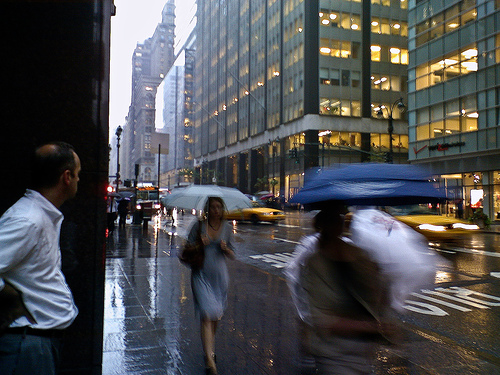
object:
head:
[314, 212, 345, 237]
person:
[292, 210, 397, 375]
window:
[318, 97, 363, 119]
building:
[0, 0, 499, 374]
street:
[100, 181, 500, 375]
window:
[402, 0, 488, 51]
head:
[19, 142, 82, 203]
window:
[415, 91, 480, 142]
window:
[319, 37, 363, 60]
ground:
[102, 189, 500, 375]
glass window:
[414, 40, 478, 92]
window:
[221, 104, 226, 111]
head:
[204, 194, 224, 218]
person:
[176, 195, 239, 375]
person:
[0, 142, 82, 375]